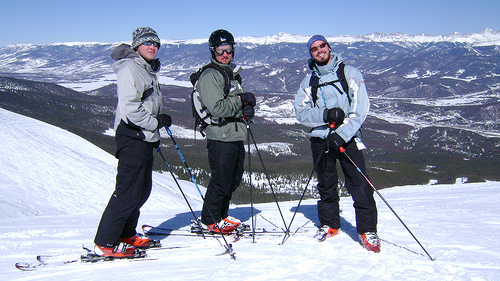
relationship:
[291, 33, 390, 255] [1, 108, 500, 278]
man at top of slope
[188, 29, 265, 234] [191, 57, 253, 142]
man in jacket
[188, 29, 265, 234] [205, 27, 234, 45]
man wearing helmet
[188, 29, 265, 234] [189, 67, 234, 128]
man with backpack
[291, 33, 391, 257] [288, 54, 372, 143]
man in jacket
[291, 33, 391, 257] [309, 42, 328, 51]
man in sunglasses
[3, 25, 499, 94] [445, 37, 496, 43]
mountains in background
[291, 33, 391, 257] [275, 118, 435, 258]
man holding ski poles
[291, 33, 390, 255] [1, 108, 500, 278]
man on slope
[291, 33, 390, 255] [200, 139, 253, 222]
man in pants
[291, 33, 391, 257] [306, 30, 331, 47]
man wearing beanie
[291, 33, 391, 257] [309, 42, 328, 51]
man wearing sunglasses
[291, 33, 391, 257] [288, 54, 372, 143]
man wearing jacket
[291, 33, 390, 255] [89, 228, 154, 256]
man have ski boots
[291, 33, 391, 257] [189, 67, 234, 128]
man wearing backpack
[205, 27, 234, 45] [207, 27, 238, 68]
helmet on head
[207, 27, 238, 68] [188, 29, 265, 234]
head of man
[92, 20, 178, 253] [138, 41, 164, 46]
man wearing sunglasses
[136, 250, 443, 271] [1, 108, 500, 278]
snow on slope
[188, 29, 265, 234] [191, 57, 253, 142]
man with jacket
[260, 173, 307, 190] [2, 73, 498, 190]
trees in valley